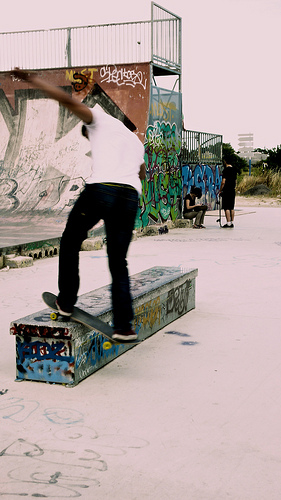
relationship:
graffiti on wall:
[0, 176, 54, 231] [132, 167, 191, 197]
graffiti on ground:
[0, 176, 54, 231] [132, 283, 226, 388]